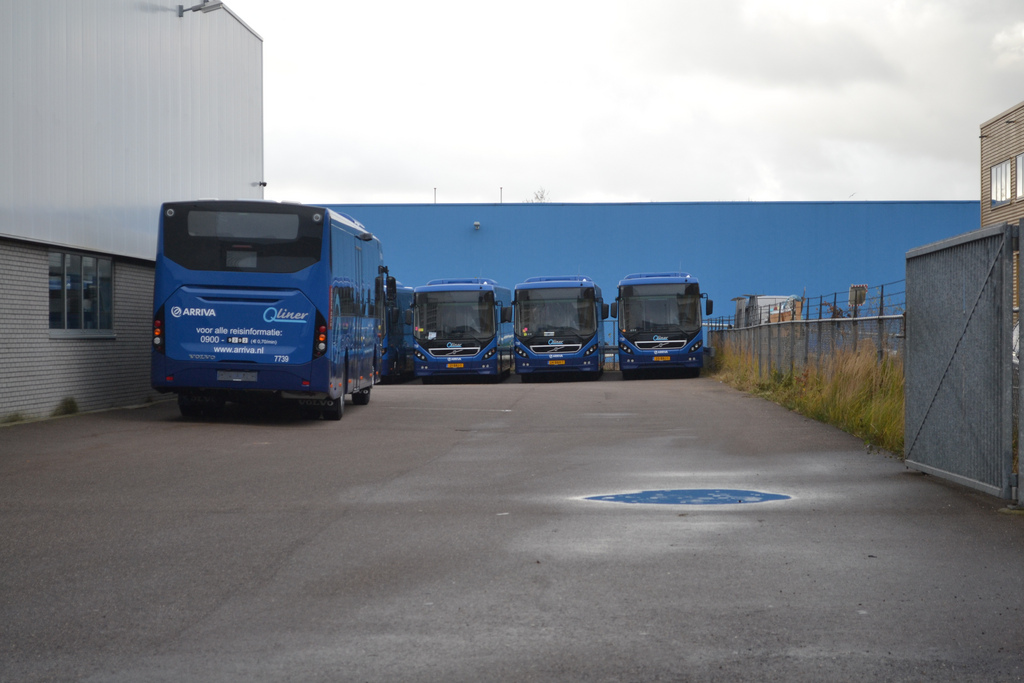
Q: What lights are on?
A: A rear lights on the bus.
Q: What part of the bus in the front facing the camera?
A: The back of the bus.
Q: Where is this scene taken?
A: In an urban parking area.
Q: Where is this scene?
A: In a bus lot.